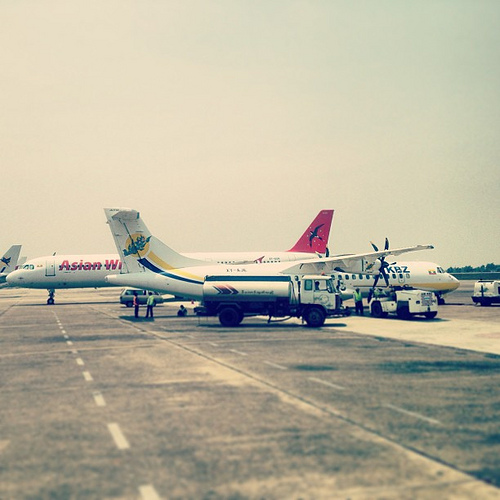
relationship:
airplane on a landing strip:
[102, 205, 460, 317] [1, 292, 484, 497]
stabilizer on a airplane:
[288, 207, 334, 256] [4, 208, 333, 318]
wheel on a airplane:
[218, 306, 239, 323] [4, 208, 333, 318]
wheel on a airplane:
[307, 307, 327, 324] [4, 208, 333, 318]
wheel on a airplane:
[47, 300, 52, 304] [102, 205, 460, 317]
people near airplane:
[120, 288, 157, 322] [102, 205, 460, 317]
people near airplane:
[120, 288, 157, 322] [4, 208, 333, 318]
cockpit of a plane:
[18, 261, 38, 273] [72, 187, 477, 335]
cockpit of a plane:
[17, 261, 44, 285] [16, 240, 294, 305]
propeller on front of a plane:
[334, 234, 394, 291] [2, 198, 467, 333]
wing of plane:
[305, 241, 437, 271] [94, 189, 465, 339]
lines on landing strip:
[49, 306, 163, 498] [42, 306, 166, 499]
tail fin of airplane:
[288, 207, 333, 256] [4, 208, 333, 318]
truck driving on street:
[202, 272, 342, 327] [29, 303, 485, 473]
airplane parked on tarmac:
[102, 205, 460, 317] [14, 305, 469, 499]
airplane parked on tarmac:
[4, 208, 333, 318] [14, 305, 469, 499]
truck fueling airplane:
[201, 275, 336, 327] [4, 208, 333, 303]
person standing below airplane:
[129, 289, 141, 319] [96, 200, 462, 297]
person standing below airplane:
[143, 288, 157, 322] [96, 200, 462, 297]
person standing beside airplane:
[144, 292, 155, 318] [102, 205, 460, 317]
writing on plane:
[58, 259, 118, 270] [6, 252, 106, 282]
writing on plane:
[385, 265, 410, 275] [100, 201, 462, 312]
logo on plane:
[201, 258, 299, 314] [82, 181, 472, 372]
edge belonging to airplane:
[383, 260, 435, 262] [102, 205, 460, 317]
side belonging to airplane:
[23, 262, 108, 281] [4, 208, 333, 318]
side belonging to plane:
[331, 265, 441, 283] [91, 205, 428, 321]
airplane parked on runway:
[52, 182, 474, 299] [47, 314, 388, 472]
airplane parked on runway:
[4, 208, 333, 303] [3, 283, 496, 498]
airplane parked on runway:
[102, 205, 460, 317] [3, 283, 496, 498]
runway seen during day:
[54, 341, 454, 498] [0, 1, 484, 494]